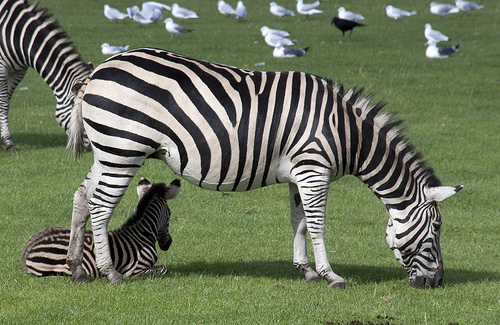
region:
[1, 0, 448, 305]
three zebras on green grass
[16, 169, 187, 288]
a baby zebra next to his mom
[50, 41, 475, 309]
adult zebra eating grass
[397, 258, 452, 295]
muzzle of zebra is black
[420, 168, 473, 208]
pointy ear of zebra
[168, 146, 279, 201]
belly of zebra is bulky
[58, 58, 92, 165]
tail of zebra is short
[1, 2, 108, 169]
a zebra eating green grass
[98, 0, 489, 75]
birds near three zebras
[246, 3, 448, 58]
a black bird in middle of white birds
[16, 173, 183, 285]
A baby zebra in the grass.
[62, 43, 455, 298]
A grown zebra grazing.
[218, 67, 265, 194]
Black and white zebra stripes.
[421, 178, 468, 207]
White ear with a black tip.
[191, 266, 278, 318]
Well maintained green grass.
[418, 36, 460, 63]
A seagull at rest in the grass.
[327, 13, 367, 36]
A black crow on the grass.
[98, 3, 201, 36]
A flock of seagulls.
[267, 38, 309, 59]
A half black, half white bird.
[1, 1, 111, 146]
A second zebra grazing, with its face obscured by the zebra in the foreground.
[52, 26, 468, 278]
zebra on a field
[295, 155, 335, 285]
leg of a zebra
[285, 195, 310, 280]
leg on a zebra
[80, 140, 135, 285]
leg of a zebra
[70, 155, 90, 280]
leg of a zebra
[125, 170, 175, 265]
zebra in a field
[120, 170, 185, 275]
zebra sitting in a field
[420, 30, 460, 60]
bird in a field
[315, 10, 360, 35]
bird in a field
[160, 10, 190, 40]
bird in a field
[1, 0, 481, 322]
zebras are eating grass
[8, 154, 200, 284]
zebra laying in grass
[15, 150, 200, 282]
zebra is laying under other zebra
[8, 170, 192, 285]
the zebra is a baby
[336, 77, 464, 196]
zebra's mane hair is black and white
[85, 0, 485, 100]
birds sitting in the grass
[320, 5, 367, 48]
the bird is black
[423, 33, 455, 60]
bird is white and gray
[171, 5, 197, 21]
the bird is white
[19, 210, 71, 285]
zebra has dirt on bottom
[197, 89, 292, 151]
pattern on side of zebra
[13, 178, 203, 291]
small zebra laying in grass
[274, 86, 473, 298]
large zebra grazing in green field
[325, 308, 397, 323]
animal droppings in grass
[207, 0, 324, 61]
group of white birds sitting in field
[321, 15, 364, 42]
black bird walking in grass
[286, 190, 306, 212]
small black spot on leg of zebra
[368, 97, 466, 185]
black and white hair on back of zebra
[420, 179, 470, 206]
black and white zebra ear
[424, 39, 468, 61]
white and grey bird resting in field